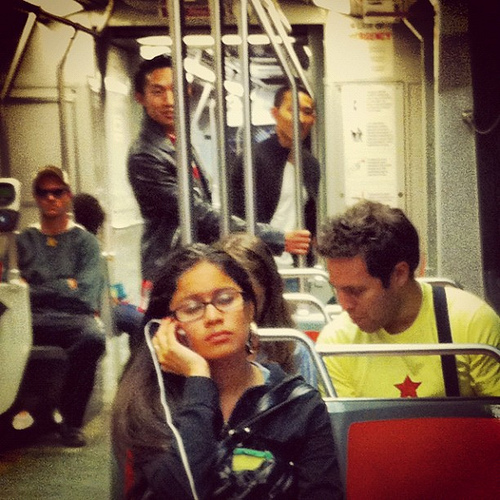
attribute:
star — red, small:
[395, 376, 422, 399]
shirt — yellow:
[310, 279, 499, 400]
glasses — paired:
[168, 289, 254, 321]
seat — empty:
[319, 346, 499, 497]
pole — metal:
[288, 86, 308, 319]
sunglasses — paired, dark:
[37, 184, 64, 199]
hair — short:
[315, 201, 421, 285]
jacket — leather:
[127, 108, 285, 281]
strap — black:
[430, 284, 460, 398]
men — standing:
[127, 54, 322, 284]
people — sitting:
[108, 197, 500, 498]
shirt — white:
[267, 159, 308, 267]